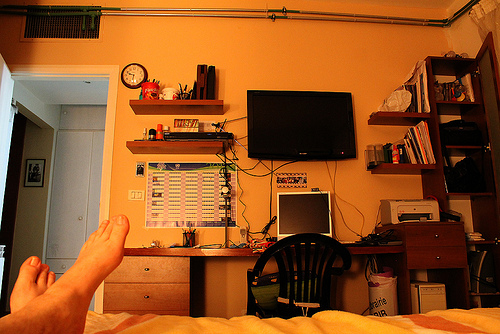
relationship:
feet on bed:
[12, 204, 135, 325] [0, 303, 498, 332]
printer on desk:
[379, 199, 441, 223] [387, 220, 475, 312]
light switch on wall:
[126, 189, 145, 201] [0, 0, 498, 330]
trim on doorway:
[7, 63, 116, 321] [1, 55, 122, 324]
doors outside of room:
[44, 118, 101, 284] [0, 0, 498, 331]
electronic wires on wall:
[210, 114, 365, 239] [0, 0, 498, 330]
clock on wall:
[117, 62, 150, 90] [0, 0, 498, 330]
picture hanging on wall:
[20, 149, 51, 194] [0, 0, 498, 330]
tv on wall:
[240, 84, 367, 167] [235, 45, 334, 79]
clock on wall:
[117, 55, 154, 89] [235, 45, 334, 79]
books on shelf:
[363, 119, 440, 162] [368, 102, 442, 181]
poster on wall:
[145, 157, 245, 234] [235, 45, 334, 79]